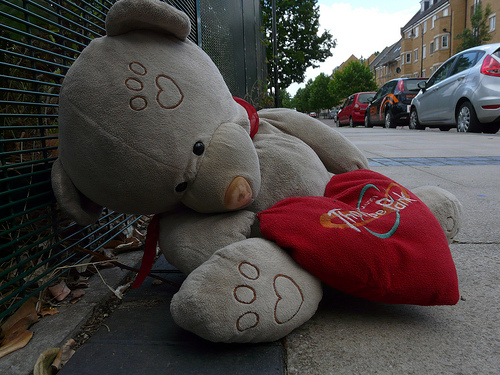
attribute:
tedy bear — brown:
[40, 0, 464, 329]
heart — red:
[244, 160, 482, 329]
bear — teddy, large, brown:
[50, 16, 460, 350]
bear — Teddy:
[98, 57, 349, 285]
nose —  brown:
[224, 175, 254, 211]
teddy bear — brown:
[49, 0, 459, 344]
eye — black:
[191, 138, 205, 155]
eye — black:
[176, 178, 188, 194]